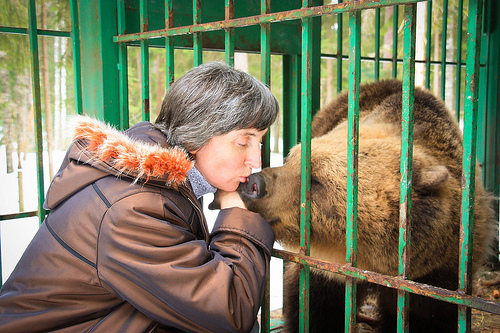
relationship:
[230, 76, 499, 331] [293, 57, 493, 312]
bear in enclosure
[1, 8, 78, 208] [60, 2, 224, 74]
trees outside of cage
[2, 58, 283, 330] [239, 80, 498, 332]
man kissing bear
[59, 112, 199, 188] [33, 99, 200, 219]
fur lining hood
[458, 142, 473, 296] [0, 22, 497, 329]
green paint4 on cage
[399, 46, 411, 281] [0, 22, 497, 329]
green paint3 on cage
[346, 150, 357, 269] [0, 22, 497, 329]
green paint2 on cage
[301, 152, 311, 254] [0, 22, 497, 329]
green paint1 on cage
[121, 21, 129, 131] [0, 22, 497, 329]
metal bars on cage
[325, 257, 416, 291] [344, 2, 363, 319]
rust on bar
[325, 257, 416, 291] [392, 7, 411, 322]
rust on bar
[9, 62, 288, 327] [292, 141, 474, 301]
woman next to bear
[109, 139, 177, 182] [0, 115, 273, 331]
fur lines coat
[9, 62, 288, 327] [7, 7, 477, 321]
woman in cage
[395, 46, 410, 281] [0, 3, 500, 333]
green paint3 chipping off cage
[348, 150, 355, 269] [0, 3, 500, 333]
green paint2 chipping off cage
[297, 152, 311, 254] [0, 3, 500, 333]
green paint1 chipping off cage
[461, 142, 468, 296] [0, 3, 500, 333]
green paint4 chipping off cage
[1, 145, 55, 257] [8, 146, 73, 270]
snow covering ground